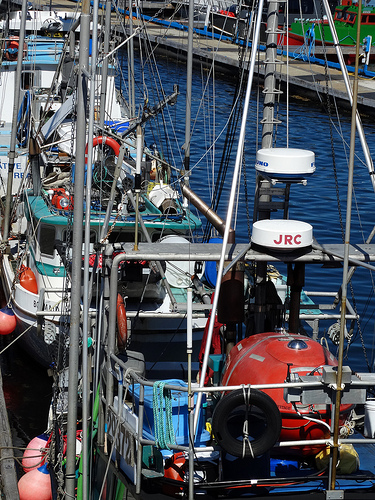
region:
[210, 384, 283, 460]
a tire on the back of the boat.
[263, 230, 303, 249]
"JRC" written on the top of the boat.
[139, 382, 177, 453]
Rope tied to the boat.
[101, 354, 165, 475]
Railing around the outside of boat.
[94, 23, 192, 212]
Wires on the top of boat.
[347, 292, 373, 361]
Chain tied to the boat.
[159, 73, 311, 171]
The water is dark blue.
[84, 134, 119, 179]
A red life wheel on the boat.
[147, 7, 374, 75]
The boat is parked at the dock.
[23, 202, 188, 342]
The boat is green and white.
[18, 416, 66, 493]
red plastic buoys hanging from boat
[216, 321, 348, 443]
large red engine on boat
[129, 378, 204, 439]
blue plastic tub on boat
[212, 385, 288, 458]
black tire hanging from side of boat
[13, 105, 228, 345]
turquoise and white boat in water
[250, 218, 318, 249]
white disc with red jrc letters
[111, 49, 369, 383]
clear dark blue water near dock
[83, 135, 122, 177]
orange lifesaver hanging from top of boat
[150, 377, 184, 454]
blue rope wrapped around boat railing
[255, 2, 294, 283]
tall silver metal mast pole with rungs for climbing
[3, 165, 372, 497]
this is a boat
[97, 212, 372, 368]
railing on the boat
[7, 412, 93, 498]
this is a bouey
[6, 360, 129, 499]
boueys attached to boat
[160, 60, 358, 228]
dark blue water way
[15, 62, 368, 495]
a bright and clear day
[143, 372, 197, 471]
rope tied on railing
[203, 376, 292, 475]
a chord on boat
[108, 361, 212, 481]
blue container on boat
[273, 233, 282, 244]
Red J on a round white thing.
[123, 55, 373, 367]
Blue water beside the boats.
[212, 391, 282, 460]
Very close black tire.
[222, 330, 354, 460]
Very large round red ball.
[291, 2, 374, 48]
The greenest boat with red accents.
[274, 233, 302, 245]
Red JRC on a white round thing.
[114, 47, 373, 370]
Dark blue water.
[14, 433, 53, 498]
Two faded red buoys on the side of the closest boat.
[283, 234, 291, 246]
Red R between J and C.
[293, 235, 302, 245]
Red C after the R.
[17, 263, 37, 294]
tank is red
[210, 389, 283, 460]
tire is attached to rail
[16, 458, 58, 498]
large orange boat anchor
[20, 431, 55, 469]
large orange boat anchor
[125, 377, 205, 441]
large blue rubbermaid type tote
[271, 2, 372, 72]
green and red boat sitting at a marina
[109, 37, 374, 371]
crystal clear blue water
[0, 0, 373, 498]
large marina filled with boats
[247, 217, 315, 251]
radar detectors on a boat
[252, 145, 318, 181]
radar detectors on a boat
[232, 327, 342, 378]
red paint on a motor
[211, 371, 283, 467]
a black round tire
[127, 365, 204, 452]
a blue plastic bin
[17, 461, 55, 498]
re round balls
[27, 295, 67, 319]
black letters ona boat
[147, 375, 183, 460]
rope on a rail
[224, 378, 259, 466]
a grey rope on a tire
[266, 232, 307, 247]
the letters JRC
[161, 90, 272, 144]
bright blue water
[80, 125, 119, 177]
a red round circle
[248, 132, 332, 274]
two small commercial radars